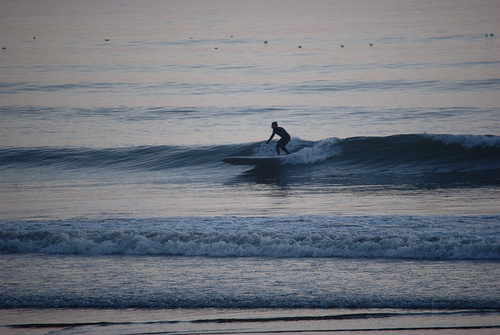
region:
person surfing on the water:
[216, 115, 328, 178]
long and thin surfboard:
[218, 147, 295, 172]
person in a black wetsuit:
[261, 115, 292, 157]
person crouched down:
[254, 117, 297, 154]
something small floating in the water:
[340, 39, 347, 52]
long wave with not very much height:
[23, 131, 497, 175]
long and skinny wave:
[8, 314, 399, 327]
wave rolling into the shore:
[7, 213, 499, 262]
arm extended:
[261, 133, 280, 144]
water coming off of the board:
[290, 142, 327, 164]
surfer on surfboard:
[267, 120, 293, 155]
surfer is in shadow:
[265, 120, 293, 153]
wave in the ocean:
[12, 133, 497, 184]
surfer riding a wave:
[0, 132, 498, 181]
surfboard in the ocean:
[222, 150, 299, 167]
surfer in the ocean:
[265, 120, 290, 156]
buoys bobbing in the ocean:
[295, 45, 301, 50]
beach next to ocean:
[3, 306, 498, 332]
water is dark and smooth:
[0, 0, 496, 331]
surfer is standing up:
[266, 120, 294, 154]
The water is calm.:
[300, 42, 442, 120]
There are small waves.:
[41, 123, 478, 299]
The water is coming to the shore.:
[50, 274, 312, 332]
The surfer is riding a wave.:
[205, 103, 339, 197]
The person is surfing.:
[218, 97, 318, 206]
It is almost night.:
[30, 21, 495, 321]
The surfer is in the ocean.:
[207, 107, 337, 197]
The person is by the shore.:
[28, 32, 488, 329]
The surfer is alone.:
[35, 21, 495, 326]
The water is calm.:
[40, 29, 146, 129]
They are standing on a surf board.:
[218, 103, 333, 194]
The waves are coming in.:
[23, 194, 465, 326]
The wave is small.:
[70, 123, 487, 199]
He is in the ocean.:
[36, 24, 468, 333]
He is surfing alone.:
[33, 23, 490, 333]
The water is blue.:
[53, 26, 488, 324]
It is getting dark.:
[52, 29, 491, 326]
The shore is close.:
[47, 298, 282, 333]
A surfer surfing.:
[214, 112, 339, 176]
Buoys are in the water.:
[92, 25, 392, 58]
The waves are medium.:
[336, 116, 494, 183]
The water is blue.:
[56, 54, 225, 139]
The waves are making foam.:
[43, 205, 493, 295]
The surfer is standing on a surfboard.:
[208, 107, 351, 184]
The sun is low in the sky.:
[62, 33, 488, 200]